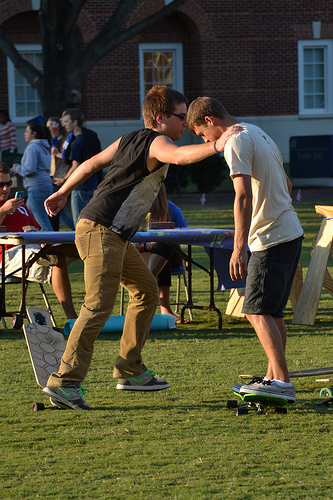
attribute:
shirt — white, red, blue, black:
[263, 173, 299, 226]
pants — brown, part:
[90, 248, 165, 290]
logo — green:
[56, 388, 79, 400]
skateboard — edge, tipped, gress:
[246, 396, 289, 412]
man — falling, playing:
[182, 84, 298, 394]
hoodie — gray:
[12, 156, 44, 192]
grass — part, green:
[188, 356, 223, 372]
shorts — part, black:
[236, 258, 300, 309]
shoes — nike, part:
[47, 372, 180, 416]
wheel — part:
[21, 399, 57, 416]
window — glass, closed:
[286, 19, 315, 120]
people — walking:
[16, 100, 80, 227]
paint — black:
[160, 249, 194, 280]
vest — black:
[58, 144, 83, 155]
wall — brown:
[118, 75, 123, 77]